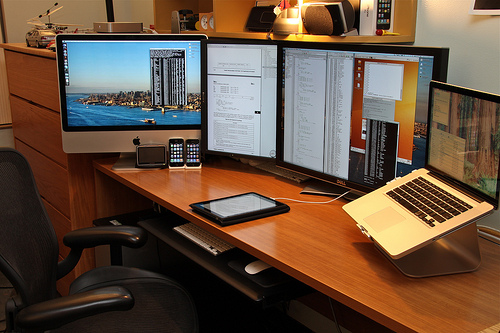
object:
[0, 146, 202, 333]
chair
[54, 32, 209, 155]
monitor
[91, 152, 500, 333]
desk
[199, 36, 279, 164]
monitor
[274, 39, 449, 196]
monitor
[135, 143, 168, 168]
smartphone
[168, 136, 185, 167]
smartphone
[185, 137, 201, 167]
smartphone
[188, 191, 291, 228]
tablet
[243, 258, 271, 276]
mouse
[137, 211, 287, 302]
drawer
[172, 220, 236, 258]
keyboard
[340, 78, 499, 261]
laptop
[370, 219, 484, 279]
stand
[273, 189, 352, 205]
cord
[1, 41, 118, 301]
file cabinet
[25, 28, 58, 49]
car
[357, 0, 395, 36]
phone box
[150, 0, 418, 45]
shelf